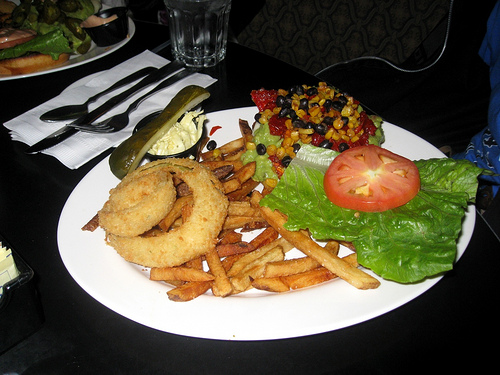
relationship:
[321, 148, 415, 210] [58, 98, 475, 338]
tomato on plate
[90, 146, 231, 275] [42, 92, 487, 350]
onion rings on plate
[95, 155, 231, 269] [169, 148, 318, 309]
onion rings over french-fries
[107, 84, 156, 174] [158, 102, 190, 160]
pickle laying over coleslaw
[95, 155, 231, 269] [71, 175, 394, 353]
onion rings on plate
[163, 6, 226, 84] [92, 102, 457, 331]
glass on top of plate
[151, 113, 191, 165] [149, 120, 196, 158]
coleslaw in cup